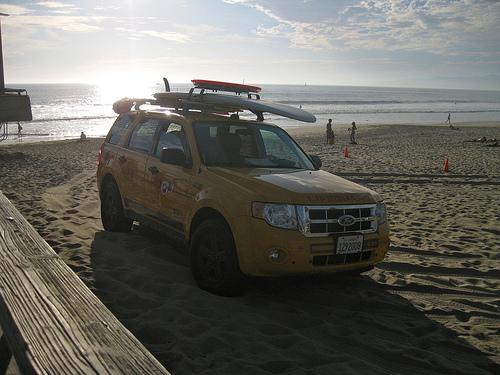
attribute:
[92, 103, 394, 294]
suv — yellow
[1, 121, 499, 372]
beach — sandy, brown, dry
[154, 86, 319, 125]
surfboard — gray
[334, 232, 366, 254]
tag — white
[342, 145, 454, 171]
cones — orange, reflective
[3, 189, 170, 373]
railing — wooden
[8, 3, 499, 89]
sky — blue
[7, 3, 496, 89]
clouds — white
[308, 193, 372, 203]
words — red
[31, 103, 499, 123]
waves — small, breaking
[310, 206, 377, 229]
grill — silver